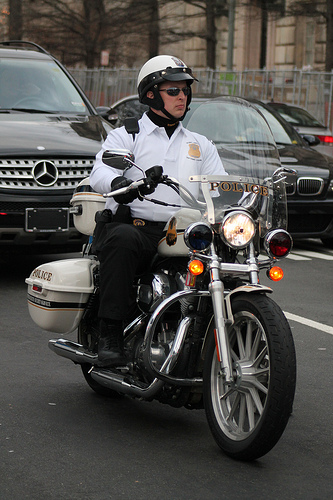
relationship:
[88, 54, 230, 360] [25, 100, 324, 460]
police officer on motorcycle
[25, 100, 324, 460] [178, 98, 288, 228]
motorcycle has windshield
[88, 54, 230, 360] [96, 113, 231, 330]
police officer in uniform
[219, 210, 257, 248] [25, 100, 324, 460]
headlight on motorcycle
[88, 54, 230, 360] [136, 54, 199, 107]
police officer wearing helmet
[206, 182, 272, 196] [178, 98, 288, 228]
decal on windshield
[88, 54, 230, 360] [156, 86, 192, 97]
police officer wearing sun glasses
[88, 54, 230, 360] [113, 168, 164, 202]
police officer wearing glove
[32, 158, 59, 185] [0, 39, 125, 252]
emblem on suv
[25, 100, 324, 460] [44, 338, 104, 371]
motorcycle has muffler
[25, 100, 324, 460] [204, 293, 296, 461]
motorcycle has wheel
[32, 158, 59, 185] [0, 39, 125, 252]
logo on suv